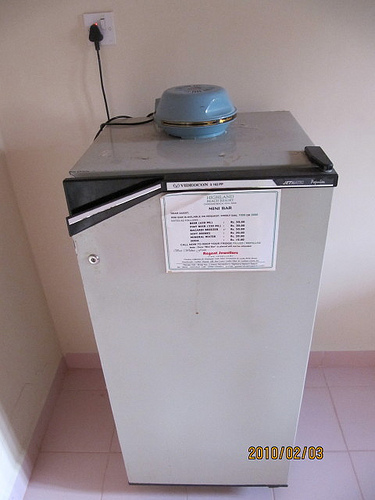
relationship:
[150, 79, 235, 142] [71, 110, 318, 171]
stabilizer on top top of the fridge